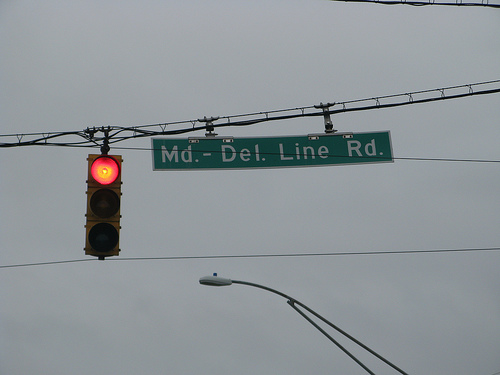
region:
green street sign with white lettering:
[145, 127, 398, 169]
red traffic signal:
[80, 146, 128, 263]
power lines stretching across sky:
[145, 244, 495, 265]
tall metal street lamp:
[194, 266, 399, 373]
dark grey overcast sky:
[70, 19, 274, 83]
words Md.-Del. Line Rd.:
[159, 137, 388, 164]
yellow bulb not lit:
[87, 186, 119, 216]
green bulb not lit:
[84, 222, 122, 254]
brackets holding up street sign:
[305, 129, 357, 146]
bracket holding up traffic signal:
[91, 116, 121, 154]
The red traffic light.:
[87, 145, 119, 182]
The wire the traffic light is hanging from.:
[14, 116, 192, 156]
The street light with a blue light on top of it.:
[194, 255, 458, 373]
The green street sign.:
[147, 133, 392, 163]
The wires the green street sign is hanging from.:
[158, 109, 360, 127]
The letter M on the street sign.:
[161, 138, 180, 162]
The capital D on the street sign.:
[223, 141, 237, 165]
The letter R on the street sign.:
[343, 137, 361, 158]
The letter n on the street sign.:
[302, 146, 315, 161]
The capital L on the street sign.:
[273, 142, 290, 162]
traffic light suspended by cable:
[71, 115, 136, 272]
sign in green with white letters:
[148, 128, 407, 169]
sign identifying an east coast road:
[147, 126, 405, 171]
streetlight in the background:
[190, 267, 370, 366]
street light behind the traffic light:
[197, 268, 366, 349]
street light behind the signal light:
[191, 267, 356, 359]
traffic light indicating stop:
[74, 127, 139, 269]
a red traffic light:
[67, 137, 134, 269]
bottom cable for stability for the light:
[2, 225, 229, 281]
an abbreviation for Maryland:
[154, 140, 199, 170]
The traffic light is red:
[71, 127, 153, 279]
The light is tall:
[180, 260, 343, 366]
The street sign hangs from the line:
[130, 119, 417, 189]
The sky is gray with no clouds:
[332, 193, 469, 286]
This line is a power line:
[347, 78, 479, 138]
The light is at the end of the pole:
[186, 260, 245, 305]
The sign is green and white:
[144, 134, 419, 166]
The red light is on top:
[76, 147, 132, 249]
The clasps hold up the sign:
[200, 110, 408, 158]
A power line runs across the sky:
[365, 212, 498, 259]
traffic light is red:
[78, 120, 125, 275]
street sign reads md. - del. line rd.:
[141, 124, 414, 179]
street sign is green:
[143, 128, 420, 180]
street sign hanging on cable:
[0, 94, 497, 174]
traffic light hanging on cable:
[71, 108, 136, 274]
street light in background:
[189, 262, 436, 374]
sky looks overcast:
[1, 97, 497, 369]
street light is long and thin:
[190, 256, 475, 371]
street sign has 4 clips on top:
[142, 95, 407, 176]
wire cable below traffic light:
[48, 103, 155, 278]